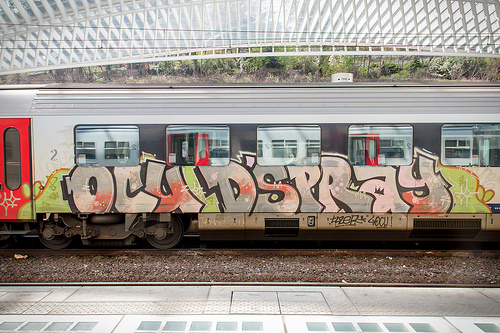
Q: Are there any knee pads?
A: No, there are no knee pads.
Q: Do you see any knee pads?
A: No, there are no knee pads.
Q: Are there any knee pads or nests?
A: No, there are no knee pads or nests.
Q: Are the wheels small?
A: Yes, the wheels are small.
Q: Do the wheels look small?
A: Yes, the wheels are small.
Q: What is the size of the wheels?
A: The wheels are small.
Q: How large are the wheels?
A: The wheels are small.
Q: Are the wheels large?
A: No, the wheels are small.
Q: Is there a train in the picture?
A: Yes, there is a train.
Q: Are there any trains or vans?
A: Yes, there is a train.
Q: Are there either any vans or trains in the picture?
A: Yes, there is a train.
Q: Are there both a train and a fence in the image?
A: Yes, there are both a train and a fence.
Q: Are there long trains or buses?
A: Yes, there is a long train.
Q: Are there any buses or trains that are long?
A: Yes, the train is long.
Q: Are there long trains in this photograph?
A: Yes, there is a long train.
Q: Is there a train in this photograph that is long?
A: Yes, there is a train that is long.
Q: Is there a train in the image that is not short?
A: Yes, there is a long train.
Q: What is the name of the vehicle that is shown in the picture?
A: The vehicle is a train.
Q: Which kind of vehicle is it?
A: The vehicle is a train.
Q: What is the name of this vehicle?
A: This is a train.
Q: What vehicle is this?
A: This is a train.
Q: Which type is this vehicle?
A: This is a train.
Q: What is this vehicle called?
A: This is a train.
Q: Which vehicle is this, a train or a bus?
A: This is a train.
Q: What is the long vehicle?
A: The vehicle is a train.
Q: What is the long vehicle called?
A: The vehicle is a train.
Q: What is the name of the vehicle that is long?
A: The vehicle is a train.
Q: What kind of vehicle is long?
A: The vehicle is a train.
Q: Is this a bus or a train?
A: This is a train.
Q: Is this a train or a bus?
A: This is a train.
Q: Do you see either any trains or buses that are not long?
A: No, there is a train but it is long.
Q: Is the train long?
A: Yes, the train is long.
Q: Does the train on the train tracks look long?
A: Yes, the train is long.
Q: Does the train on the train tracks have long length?
A: Yes, the train is long.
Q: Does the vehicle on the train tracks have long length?
A: Yes, the train is long.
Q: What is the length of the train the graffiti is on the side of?
A: The train is long.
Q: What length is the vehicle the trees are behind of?
A: The train is long.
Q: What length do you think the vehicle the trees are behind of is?
A: The train is long.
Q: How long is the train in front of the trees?
A: The train is long.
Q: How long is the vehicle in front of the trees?
A: The train is long.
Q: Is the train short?
A: No, the train is long.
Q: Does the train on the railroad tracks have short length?
A: No, the train is long.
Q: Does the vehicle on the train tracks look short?
A: No, the train is long.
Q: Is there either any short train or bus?
A: No, there is a train but it is long.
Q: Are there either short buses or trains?
A: No, there is a train but it is long.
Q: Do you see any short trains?
A: No, there is a train but it is long.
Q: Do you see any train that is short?
A: No, there is a train but it is long.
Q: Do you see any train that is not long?
A: No, there is a train but it is long.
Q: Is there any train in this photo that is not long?
A: No, there is a train but it is long.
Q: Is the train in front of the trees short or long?
A: The train is long.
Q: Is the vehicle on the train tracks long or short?
A: The train is long.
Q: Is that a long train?
A: Yes, that is a long train.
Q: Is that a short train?
A: No, that is a long train.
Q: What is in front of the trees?
A: The train is in front of the trees.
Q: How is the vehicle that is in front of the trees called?
A: The vehicle is a train.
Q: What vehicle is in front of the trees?
A: The vehicle is a train.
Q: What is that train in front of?
A: The train is in front of the trees.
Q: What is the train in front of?
A: The train is in front of the trees.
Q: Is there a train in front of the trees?
A: Yes, there is a train in front of the trees.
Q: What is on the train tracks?
A: The train is on the train tracks.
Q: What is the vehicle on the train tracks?
A: The vehicle is a train.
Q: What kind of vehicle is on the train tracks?
A: The vehicle is a train.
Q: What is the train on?
A: The train is on the railroad tracks.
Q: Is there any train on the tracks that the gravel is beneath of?
A: Yes, there is a train on the tracks.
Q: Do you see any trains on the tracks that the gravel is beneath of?
A: Yes, there is a train on the tracks.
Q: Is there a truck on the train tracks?
A: No, there is a train on the train tracks.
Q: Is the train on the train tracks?
A: Yes, the train is on the train tracks.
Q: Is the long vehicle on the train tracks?
A: Yes, the train is on the train tracks.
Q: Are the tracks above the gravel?
A: Yes, the tracks are above the gravel.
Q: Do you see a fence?
A: Yes, there is a fence.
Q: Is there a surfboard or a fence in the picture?
A: Yes, there is a fence.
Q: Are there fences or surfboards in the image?
A: Yes, there is a fence.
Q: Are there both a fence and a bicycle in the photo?
A: No, there is a fence but no bicycles.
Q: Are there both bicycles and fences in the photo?
A: No, there is a fence but no bicycles.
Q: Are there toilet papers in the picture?
A: No, there are no toilet papers.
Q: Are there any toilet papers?
A: No, there are no toilet papers.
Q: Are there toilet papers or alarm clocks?
A: No, there are no toilet papers or alarm clocks.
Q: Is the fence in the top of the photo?
A: Yes, the fence is in the top of the image.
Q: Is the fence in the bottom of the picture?
A: No, the fence is in the top of the image.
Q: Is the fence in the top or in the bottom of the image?
A: The fence is in the top of the image.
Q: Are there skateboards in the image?
A: No, there are no skateboards.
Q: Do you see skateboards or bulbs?
A: No, there are no skateboards or bulbs.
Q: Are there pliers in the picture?
A: No, there are no pliers.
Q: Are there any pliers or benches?
A: No, there are no pliers or benches.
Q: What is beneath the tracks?
A: The gravel is beneath the tracks.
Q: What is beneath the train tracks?
A: The gravel is beneath the tracks.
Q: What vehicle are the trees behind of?
A: The trees are behind the train.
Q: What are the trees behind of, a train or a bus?
A: The trees are behind a train.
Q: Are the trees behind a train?
A: Yes, the trees are behind a train.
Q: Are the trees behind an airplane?
A: No, the trees are behind a train.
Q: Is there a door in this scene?
A: Yes, there is a door.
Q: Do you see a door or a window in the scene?
A: Yes, there is a door.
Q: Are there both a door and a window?
A: Yes, there are both a door and a window.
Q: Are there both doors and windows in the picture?
A: Yes, there are both a door and windows.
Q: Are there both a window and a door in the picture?
A: Yes, there are both a door and a window.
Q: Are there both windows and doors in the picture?
A: Yes, there are both a door and windows.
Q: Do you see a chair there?
A: No, there are no chairs.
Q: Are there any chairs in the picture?
A: No, there are no chairs.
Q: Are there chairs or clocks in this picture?
A: No, there are no chairs or clocks.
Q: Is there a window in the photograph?
A: Yes, there is a window.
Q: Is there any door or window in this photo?
A: Yes, there is a window.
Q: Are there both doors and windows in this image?
A: Yes, there are both a window and doors.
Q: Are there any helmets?
A: No, there are no helmets.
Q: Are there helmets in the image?
A: No, there are no helmets.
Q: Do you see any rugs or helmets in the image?
A: No, there are no helmets or rugs.